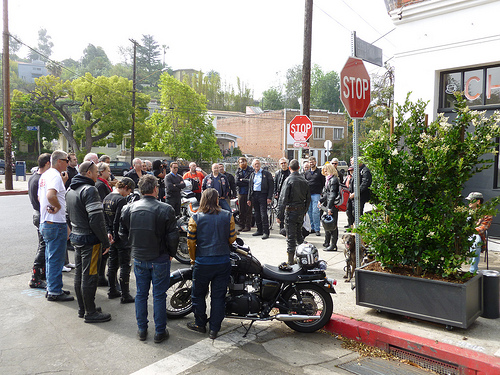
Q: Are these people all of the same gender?
A: No, they are both male and female.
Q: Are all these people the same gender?
A: No, they are both male and female.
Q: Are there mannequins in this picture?
A: No, there are no mannequins.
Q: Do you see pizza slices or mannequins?
A: No, there are no mannequins or pizza slices.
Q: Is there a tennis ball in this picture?
A: No, there are no tennis balls.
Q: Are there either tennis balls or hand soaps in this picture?
A: No, there are no tennis balls or hand soaps.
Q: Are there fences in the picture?
A: No, there are no fences.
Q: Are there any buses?
A: No, there are no buses.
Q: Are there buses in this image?
A: No, there are no buses.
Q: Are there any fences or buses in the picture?
A: No, there are no buses or fences.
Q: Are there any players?
A: No, there are no players.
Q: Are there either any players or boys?
A: No, there are no players or boys.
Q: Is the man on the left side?
A: Yes, the man is on the left of the image.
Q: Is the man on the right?
A: No, the man is on the left of the image.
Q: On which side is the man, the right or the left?
A: The man is on the left of the image.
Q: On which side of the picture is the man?
A: The man is on the left of the image.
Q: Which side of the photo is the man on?
A: The man is on the left of the image.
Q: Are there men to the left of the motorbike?
A: Yes, there is a man to the left of the motorbike.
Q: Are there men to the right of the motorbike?
A: No, the man is to the left of the motorbike.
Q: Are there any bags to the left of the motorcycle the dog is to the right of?
A: No, there is a man to the left of the motorbike.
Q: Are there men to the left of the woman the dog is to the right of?
A: Yes, there is a man to the left of the woman.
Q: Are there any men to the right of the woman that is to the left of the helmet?
A: No, the man is to the left of the woman.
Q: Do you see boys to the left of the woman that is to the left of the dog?
A: No, there is a man to the left of the woman.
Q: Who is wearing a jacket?
A: The man is wearing a jacket.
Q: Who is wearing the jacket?
A: The man is wearing a jacket.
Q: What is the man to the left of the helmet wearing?
A: The man is wearing a jacket.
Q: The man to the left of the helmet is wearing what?
A: The man is wearing a jacket.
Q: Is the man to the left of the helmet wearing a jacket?
A: Yes, the man is wearing a jacket.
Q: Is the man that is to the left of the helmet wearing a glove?
A: No, the man is wearing a jacket.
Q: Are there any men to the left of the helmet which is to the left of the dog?
A: Yes, there is a man to the left of the helmet.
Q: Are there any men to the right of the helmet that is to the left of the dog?
A: No, the man is to the left of the helmet.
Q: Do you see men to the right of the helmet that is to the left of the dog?
A: No, the man is to the left of the helmet.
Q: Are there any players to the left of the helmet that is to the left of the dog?
A: No, there is a man to the left of the helmet.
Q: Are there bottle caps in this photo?
A: No, there are no bottle caps.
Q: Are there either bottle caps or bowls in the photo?
A: No, there are no bottle caps or bowls.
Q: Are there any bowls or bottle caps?
A: No, there are no bottle caps or bowls.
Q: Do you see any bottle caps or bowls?
A: No, there are no bottle caps or bowls.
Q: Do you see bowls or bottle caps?
A: No, there are no bottle caps or bowls.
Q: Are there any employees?
A: No, there are no employees.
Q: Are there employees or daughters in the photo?
A: No, there are no employees or daughters.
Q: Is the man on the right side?
A: No, the man is on the left of the image.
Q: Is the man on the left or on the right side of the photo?
A: The man is on the left of the image.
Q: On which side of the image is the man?
A: The man is on the left of the image.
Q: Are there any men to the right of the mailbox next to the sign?
A: Yes, there is a man to the right of the mailbox.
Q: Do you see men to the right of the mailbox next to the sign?
A: Yes, there is a man to the right of the mailbox.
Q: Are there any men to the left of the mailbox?
A: No, the man is to the right of the mailbox.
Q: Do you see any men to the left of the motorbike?
A: Yes, there is a man to the left of the motorbike.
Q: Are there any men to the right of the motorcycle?
A: No, the man is to the left of the motorcycle.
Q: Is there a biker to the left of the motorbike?
A: No, there is a man to the left of the motorbike.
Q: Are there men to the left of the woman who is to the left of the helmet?
A: Yes, there is a man to the left of the woman.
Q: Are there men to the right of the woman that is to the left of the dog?
A: No, the man is to the left of the woman.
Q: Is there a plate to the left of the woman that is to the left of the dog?
A: No, there is a man to the left of the woman.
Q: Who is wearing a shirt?
A: The man is wearing a shirt.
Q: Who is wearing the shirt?
A: The man is wearing a shirt.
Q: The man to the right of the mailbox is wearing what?
A: The man is wearing a shirt.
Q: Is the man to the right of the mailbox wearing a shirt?
A: Yes, the man is wearing a shirt.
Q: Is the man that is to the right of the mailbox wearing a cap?
A: No, the man is wearing a shirt.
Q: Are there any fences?
A: No, there are no fences.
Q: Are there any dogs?
A: Yes, there is a dog.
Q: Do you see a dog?
A: Yes, there is a dog.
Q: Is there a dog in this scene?
A: Yes, there is a dog.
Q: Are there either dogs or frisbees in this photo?
A: Yes, there is a dog.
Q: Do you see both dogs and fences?
A: No, there is a dog but no fences.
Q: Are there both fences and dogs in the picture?
A: No, there is a dog but no fences.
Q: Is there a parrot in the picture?
A: No, there are no parrots.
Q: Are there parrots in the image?
A: No, there are no parrots.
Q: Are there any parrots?
A: No, there are no parrots.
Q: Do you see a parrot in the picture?
A: No, there are no parrots.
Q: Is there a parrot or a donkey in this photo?
A: No, there are no parrots or donkeys.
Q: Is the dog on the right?
A: Yes, the dog is on the right of the image.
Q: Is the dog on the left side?
A: No, the dog is on the right of the image.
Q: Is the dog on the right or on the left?
A: The dog is on the right of the image.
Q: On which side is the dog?
A: The dog is on the right of the image.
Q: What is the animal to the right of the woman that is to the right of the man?
A: The animal is a dog.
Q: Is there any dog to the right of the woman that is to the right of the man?
A: Yes, there is a dog to the right of the woman.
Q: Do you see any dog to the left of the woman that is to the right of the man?
A: No, the dog is to the right of the woman.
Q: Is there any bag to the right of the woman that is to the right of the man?
A: No, there is a dog to the right of the woman.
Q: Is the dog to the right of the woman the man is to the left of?
A: Yes, the dog is to the right of the woman.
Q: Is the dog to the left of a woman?
A: No, the dog is to the right of a woman.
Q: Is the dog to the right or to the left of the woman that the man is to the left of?
A: The dog is to the right of the woman.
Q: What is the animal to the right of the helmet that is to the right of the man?
A: The animal is a dog.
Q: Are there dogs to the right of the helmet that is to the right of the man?
A: Yes, there is a dog to the right of the helmet.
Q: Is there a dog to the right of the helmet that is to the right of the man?
A: Yes, there is a dog to the right of the helmet.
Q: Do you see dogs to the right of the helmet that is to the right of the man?
A: Yes, there is a dog to the right of the helmet.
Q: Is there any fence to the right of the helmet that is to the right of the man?
A: No, there is a dog to the right of the helmet.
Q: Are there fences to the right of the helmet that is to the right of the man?
A: No, there is a dog to the right of the helmet.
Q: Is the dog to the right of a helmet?
A: Yes, the dog is to the right of a helmet.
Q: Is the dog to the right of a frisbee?
A: No, the dog is to the right of a helmet.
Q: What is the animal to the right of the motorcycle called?
A: The animal is a dog.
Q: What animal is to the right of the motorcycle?
A: The animal is a dog.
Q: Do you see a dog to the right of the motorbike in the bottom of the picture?
A: Yes, there is a dog to the right of the motorbike.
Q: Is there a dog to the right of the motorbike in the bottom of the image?
A: Yes, there is a dog to the right of the motorbike.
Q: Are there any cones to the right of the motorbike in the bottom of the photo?
A: No, there is a dog to the right of the motorbike.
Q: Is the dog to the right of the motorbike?
A: Yes, the dog is to the right of the motorbike.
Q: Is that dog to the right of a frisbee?
A: No, the dog is to the right of the motorbike.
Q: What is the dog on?
A: The dog is on the stop sign.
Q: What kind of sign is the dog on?
A: The dog is on the stop sign.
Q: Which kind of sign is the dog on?
A: The dog is on the stop sign.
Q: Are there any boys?
A: No, there are no boys.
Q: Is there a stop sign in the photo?
A: Yes, there is a stop sign.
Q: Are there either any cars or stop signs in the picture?
A: Yes, there is a stop sign.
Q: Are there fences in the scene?
A: No, there are no fences.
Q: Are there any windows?
A: Yes, there is a window.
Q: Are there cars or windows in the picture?
A: Yes, there is a window.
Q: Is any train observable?
A: No, there are no trains.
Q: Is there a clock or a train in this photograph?
A: No, there are no trains or clocks.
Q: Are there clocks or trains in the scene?
A: No, there are no trains or clocks.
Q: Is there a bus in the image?
A: No, there are no buses.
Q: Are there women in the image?
A: Yes, there is a woman.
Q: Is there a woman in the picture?
A: Yes, there is a woman.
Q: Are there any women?
A: Yes, there is a woman.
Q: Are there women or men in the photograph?
A: Yes, there is a woman.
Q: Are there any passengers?
A: No, there are no passengers.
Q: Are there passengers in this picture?
A: No, there are no passengers.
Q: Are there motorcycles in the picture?
A: Yes, there is a motorcycle.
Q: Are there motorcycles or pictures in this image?
A: Yes, there is a motorcycle.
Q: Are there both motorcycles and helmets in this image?
A: Yes, there are both a motorcycle and a helmet.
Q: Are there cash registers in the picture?
A: No, there are no cash registers.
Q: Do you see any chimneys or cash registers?
A: No, there are no cash registers or chimneys.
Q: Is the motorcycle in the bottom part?
A: Yes, the motorcycle is in the bottom of the image.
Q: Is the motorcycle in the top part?
A: No, the motorcycle is in the bottom of the image.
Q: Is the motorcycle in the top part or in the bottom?
A: The motorcycle is in the bottom of the image.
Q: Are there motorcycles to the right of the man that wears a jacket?
A: Yes, there is a motorcycle to the right of the man.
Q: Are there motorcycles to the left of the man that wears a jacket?
A: No, the motorcycle is to the right of the man.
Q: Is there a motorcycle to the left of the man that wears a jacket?
A: No, the motorcycle is to the right of the man.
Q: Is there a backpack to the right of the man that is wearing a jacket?
A: No, there is a motorcycle to the right of the man.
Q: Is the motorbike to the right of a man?
A: Yes, the motorbike is to the right of a man.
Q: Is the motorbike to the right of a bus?
A: No, the motorbike is to the right of a man.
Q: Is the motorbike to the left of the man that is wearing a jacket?
A: No, the motorbike is to the right of the man.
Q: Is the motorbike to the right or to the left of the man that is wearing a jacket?
A: The motorbike is to the right of the man.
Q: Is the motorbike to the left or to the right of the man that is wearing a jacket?
A: The motorbike is to the right of the man.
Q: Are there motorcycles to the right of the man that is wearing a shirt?
A: Yes, there is a motorcycle to the right of the man.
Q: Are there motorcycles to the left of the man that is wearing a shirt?
A: No, the motorcycle is to the right of the man.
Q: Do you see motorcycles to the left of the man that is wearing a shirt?
A: No, the motorcycle is to the right of the man.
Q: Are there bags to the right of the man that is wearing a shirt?
A: No, there is a motorcycle to the right of the man.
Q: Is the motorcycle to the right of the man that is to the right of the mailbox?
A: Yes, the motorcycle is to the right of the man.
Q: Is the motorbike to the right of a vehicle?
A: No, the motorbike is to the right of the man.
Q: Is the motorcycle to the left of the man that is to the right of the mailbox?
A: No, the motorcycle is to the right of the man.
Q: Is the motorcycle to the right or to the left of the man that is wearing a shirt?
A: The motorcycle is to the right of the man.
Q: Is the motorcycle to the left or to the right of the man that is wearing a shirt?
A: The motorcycle is to the right of the man.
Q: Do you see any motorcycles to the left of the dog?
A: Yes, there is a motorcycle to the left of the dog.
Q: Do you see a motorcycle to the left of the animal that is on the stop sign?
A: Yes, there is a motorcycle to the left of the dog.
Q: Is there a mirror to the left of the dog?
A: No, there is a motorcycle to the left of the dog.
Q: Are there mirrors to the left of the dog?
A: No, there is a motorcycle to the left of the dog.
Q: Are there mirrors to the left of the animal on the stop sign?
A: No, there is a motorcycle to the left of the dog.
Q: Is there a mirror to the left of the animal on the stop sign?
A: No, there is a motorcycle to the left of the dog.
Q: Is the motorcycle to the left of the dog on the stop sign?
A: Yes, the motorcycle is to the left of the dog.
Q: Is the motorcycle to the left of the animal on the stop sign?
A: Yes, the motorcycle is to the left of the dog.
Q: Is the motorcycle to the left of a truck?
A: No, the motorcycle is to the left of the dog.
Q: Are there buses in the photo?
A: No, there are no buses.